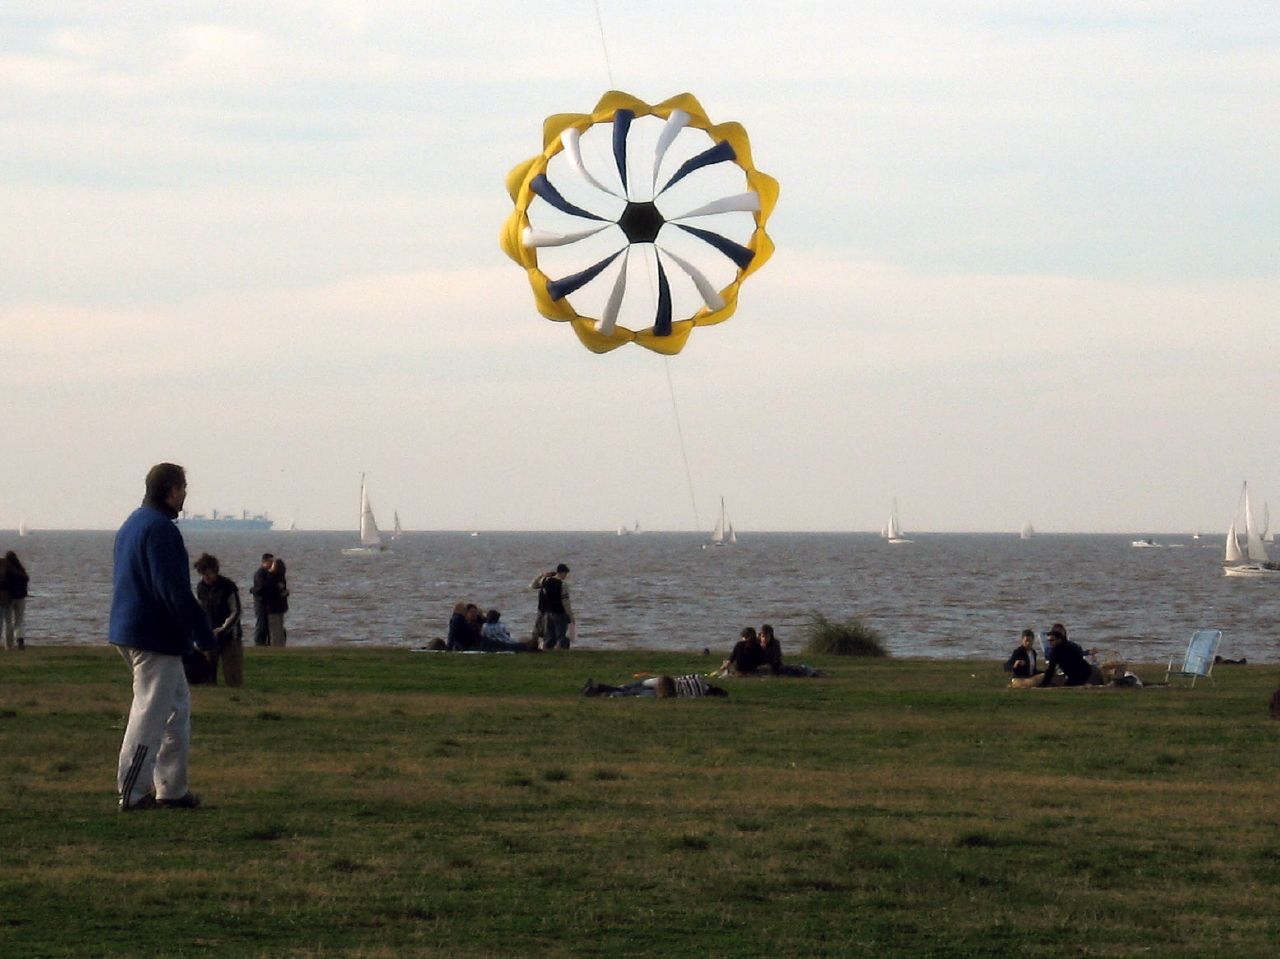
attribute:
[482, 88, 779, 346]
kite — black , yellow, white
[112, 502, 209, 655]
coat — blue 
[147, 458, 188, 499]
hair — dark 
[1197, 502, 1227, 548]
sail — white 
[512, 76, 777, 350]
kite — round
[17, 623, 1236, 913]
field — grassy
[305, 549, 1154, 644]
water —  large body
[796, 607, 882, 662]
bush — small 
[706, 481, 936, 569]
ship — large distant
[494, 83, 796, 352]
border — yellow 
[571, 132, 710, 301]
blades — silver , black 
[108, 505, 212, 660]
coat — blue 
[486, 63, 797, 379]
kite — yellow, blue, white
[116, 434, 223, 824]
man —  walking 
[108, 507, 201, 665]
coat — blue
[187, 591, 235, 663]
bag — plastic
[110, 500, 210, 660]
jacket — blue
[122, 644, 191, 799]
pants — white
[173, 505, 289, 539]
ship — large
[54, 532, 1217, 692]
water — large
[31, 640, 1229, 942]
shoreline — grassy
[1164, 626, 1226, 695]
chair — blue